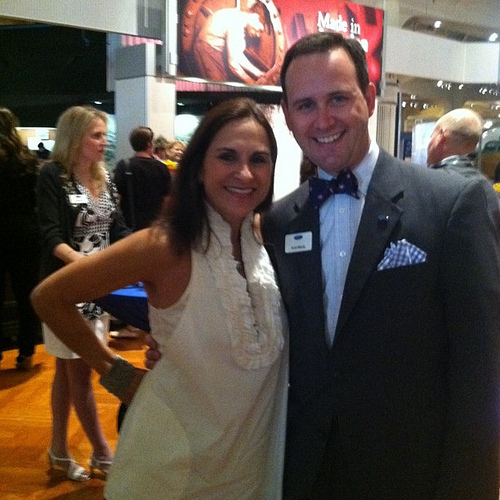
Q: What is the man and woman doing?
A: Smiling.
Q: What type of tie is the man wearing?
A: Bowtie.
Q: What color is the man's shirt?
A: Blue.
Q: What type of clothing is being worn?
A: Formal.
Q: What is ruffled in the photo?
A: Woman's top.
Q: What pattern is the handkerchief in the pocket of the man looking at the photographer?
A: Checkered.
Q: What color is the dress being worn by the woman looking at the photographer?
A: White.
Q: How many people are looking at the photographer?
A: Two.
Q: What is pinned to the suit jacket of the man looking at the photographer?
A: Nametag.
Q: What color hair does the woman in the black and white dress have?
A: Blonde.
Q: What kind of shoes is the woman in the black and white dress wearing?
A: High heels.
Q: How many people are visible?
A: Eight.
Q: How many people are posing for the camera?
A: Two.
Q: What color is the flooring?
A: Brown.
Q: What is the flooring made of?
A: Wood.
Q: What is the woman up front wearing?
A: White blouse.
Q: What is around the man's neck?
A: Bow tie.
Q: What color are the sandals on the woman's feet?
A: White.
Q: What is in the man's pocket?
A: Handkerchief.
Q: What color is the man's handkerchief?
A: Blue and white.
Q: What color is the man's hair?
A: Brown.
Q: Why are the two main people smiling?
A: Posing for picture.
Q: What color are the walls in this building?
A: White.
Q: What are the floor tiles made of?
A: Wood.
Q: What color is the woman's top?
A: White.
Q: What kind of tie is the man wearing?
A: A bow tie.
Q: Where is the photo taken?
A: A event.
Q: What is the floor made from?
A: Wood.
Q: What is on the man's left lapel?
A: A name tag.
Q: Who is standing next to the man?
A: A woman.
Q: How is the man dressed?
A: In a suit.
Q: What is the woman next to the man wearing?
A: White.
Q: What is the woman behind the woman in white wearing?
A: A black and white dress.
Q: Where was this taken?
A: At a reception.